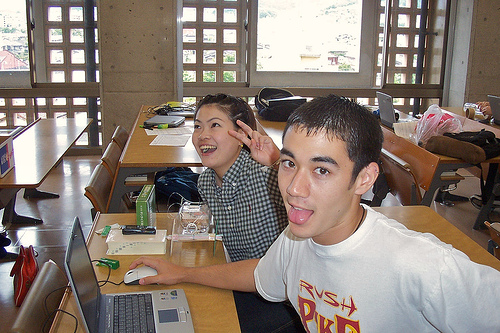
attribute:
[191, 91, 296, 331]
girl — sitting, smiling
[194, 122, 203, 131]
eye — brown, open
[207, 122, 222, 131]
eye — brown, open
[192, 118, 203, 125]
eyebrow — brown, arched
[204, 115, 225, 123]
eyebrow — brown, arched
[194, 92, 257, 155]
hair — brown, styled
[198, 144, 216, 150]
teeth — white, straight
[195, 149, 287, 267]
shirt — checkered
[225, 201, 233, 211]
button — round, white